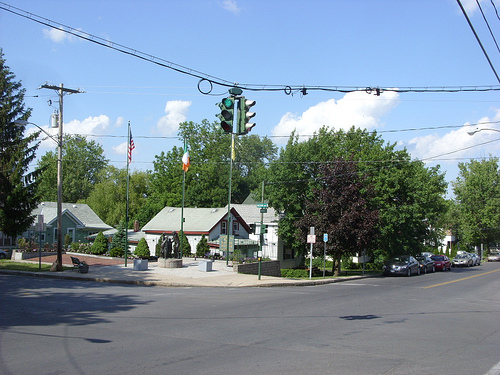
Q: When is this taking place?
A: Daytime.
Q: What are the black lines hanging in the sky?
A: Power lines.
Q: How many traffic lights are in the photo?
A: One.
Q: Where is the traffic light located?
A: Corner.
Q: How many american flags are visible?
A: One.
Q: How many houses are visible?
A: Three.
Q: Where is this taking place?
A: In a city street.